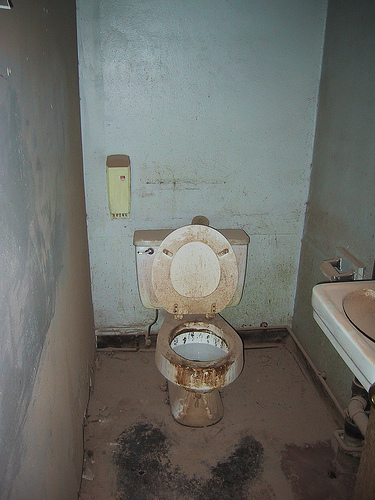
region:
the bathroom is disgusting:
[28, 132, 372, 497]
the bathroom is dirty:
[17, 204, 366, 497]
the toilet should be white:
[96, 215, 300, 444]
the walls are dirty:
[85, 133, 372, 377]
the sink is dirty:
[312, 272, 371, 400]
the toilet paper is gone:
[290, 238, 371, 318]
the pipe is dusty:
[327, 384, 374, 439]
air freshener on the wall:
[91, 132, 162, 240]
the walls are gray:
[52, 15, 372, 217]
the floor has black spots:
[81, 397, 275, 496]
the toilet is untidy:
[110, 263, 294, 458]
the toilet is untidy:
[147, 292, 247, 487]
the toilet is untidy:
[166, 321, 232, 406]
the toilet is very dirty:
[152, 273, 282, 416]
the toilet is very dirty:
[104, 212, 260, 427]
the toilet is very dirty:
[161, 257, 244, 359]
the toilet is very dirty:
[125, 233, 303, 489]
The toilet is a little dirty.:
[127, 222, 266, 426]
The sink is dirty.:
[318, 276, 373, 371]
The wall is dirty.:
[254, 205, 289, 300]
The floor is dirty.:
[247, 393, 309, 480]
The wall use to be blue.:
[209, 155, 287, 208]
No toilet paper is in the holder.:
[310, 242, 366, 292]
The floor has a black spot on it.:
[107, 422, 263, 496]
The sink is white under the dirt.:
[301, 269, 374, 397]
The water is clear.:
[162, 340, 232, 364]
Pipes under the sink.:
[306, 369, 368, 475]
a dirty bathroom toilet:
[92, 184, 279, 424]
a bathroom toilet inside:
[118, 204, 310, 444]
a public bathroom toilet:
[61, 176, 292, 455]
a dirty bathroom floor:
[85, 328, 359, 497]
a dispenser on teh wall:
[99, 133, 167, 240]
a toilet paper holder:
[295, 219, 369, 280]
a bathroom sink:
[286, 246, 369, 391]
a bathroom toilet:
[100, 198, 268, 480]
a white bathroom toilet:
[91, 216, 258, 456]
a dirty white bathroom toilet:
[137, 200, 284, 425]